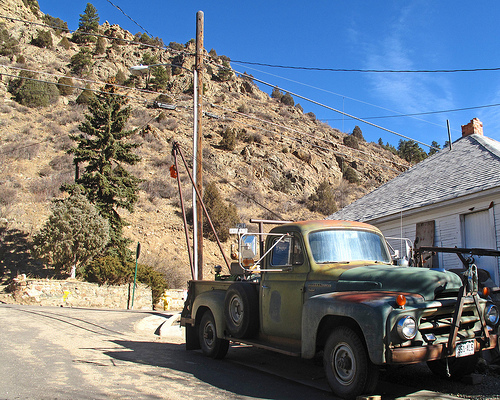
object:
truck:
[180, 218, 499, 399]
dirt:
[0, 303, 364, 399]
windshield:
[307, 229, 391, 264]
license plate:
[456, 339, 476, 357]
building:
[323, 118, 500, 289]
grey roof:
[324, 117, 500, 222]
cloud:
[347, 1, 500, 136]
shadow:
[103, 340, 499, 400]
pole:
[197, 10, 205, 279]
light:
[398, 316, 417, 340]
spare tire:
[224, 282, 259, 338]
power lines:
[0, 0, 499, 172]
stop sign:
[130, 242, 141, 309]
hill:
[0, 1, 425, 305]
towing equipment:
[171, 142, 258, 282]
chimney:
[460, 117, 482, 138]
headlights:
[396, 304, 500, 340]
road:
[0, 303, 397, 400]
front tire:
[322, 326, 379, 398]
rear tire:
[198, 309, 229, 359]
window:
[271, 233, 304, 268]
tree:
[36, 191, 111, 281]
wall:
[0, 276, 187, 312]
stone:
[1, 276, 189, 313]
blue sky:
[35, 1, 500, 154]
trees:
[77, 83, 134, 221]